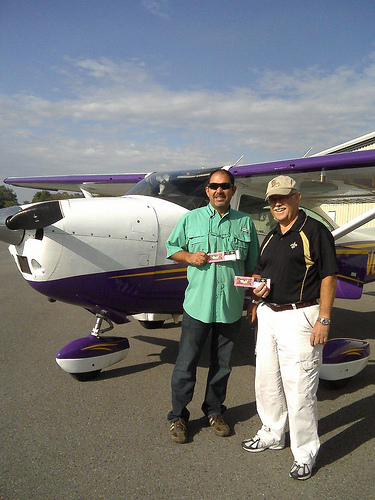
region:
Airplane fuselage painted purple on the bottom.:
[2, 193, 370, 319]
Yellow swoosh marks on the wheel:
[80, 334, 117, 355]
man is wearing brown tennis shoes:
[166, 406, 230, 441]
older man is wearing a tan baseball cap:
[264, 173, 301, 225]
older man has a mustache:
[271, 198, 288, 219]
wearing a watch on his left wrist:
[310, 310, 332, 344]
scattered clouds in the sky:
[9, 29, 297, 154]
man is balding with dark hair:
[205, 167, 235, 185]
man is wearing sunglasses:
[205, 179, 235, 191]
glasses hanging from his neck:
[206, 204, 233, 238]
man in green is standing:
[170, 168, 262, 447]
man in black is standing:
[248, 175, 335, 478]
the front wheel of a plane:
[56, 333, 130, 381]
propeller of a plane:
[2, 193, 67, 262]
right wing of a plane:
[5, 174, 136, 197]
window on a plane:
[128, 168, 213, 212]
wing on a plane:
[234, 147, 374, 207]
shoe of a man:
[243, 431, 284, 451]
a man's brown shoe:
[202, 408, 230, 436]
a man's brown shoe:
[167, 417, 186, 443]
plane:
[3, 188, 157, 392]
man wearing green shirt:
[173, 205, 250, 320]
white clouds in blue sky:
[46, 44, 80, 71]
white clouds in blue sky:
[249, 73, 313, 132]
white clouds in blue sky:
[122, 14, 185, 64]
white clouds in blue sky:
[74, 20, 140, 98]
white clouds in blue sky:
[0, 65, 64, 132]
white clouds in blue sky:
[268, 15, 343, 67]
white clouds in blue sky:
[243, 84, 293, 126]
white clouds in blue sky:
[76, 86, 110, 108]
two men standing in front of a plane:
[167, 168, 338, 478]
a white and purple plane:
[2, 150, 372, 381]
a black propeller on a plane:
[6, 200, 63, 231]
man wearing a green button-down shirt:
[166, 203, 258, 320]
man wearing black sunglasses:
[208, 180, 233, 190]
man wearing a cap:
[264, 174, 302, 198]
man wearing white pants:
[255, 303, 323, 466]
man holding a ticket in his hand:
[234, 276, 270, 288]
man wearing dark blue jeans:
[168, 308, 241, 420]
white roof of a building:
[307, 130, 374, 156]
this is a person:
[161, 147, 255, 460]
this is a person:
[248, 166, 343, 493]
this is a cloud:
[76, 96, 139, 137]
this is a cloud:
[142, 67, 223, 138]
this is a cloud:
[38, 101, 96, 141]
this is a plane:
[1, 129, 373, 409]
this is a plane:
[27, 212, 133, 327]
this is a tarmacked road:
[58, 405, 195, 478]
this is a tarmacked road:
[19, 375, 77, 467]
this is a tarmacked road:
[189, 438, 265, 485]